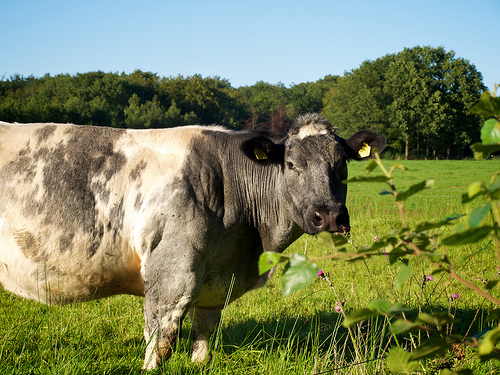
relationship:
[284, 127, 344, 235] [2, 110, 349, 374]
face of cow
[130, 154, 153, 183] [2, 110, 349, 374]
spot on cow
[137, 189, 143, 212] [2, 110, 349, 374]
spot on cow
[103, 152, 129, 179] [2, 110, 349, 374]
spot on cow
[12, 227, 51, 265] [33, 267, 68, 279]
spot next to spot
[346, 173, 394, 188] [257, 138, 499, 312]
leaf on branch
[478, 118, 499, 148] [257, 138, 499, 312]
leaf on branch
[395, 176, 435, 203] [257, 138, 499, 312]
leaf on branch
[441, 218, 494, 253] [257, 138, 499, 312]
leaf on branch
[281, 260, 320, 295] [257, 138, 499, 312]
leaf on branch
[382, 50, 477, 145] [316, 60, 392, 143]
tree next to tree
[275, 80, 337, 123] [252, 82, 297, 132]
tree next to tree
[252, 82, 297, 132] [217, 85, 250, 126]
tree next to tree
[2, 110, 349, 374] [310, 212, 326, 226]
cow has nostril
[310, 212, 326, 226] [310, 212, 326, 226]
nostril has nostril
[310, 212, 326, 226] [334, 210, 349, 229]
nostril has nostril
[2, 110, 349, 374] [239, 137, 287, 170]
cow has right ear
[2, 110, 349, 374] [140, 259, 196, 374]
cow has leg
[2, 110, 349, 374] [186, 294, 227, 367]
cow has leg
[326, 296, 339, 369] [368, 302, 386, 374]
grass leaf next to grass leaf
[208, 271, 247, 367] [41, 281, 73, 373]
grass leaf next to grass leaf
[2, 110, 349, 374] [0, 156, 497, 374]
cow standing in meadow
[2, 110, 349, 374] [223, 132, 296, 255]
cow has neck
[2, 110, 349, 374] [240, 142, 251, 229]
cow has wrinkle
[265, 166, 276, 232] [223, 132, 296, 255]
wrinkle along neck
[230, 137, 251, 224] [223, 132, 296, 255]
wrinkle along neck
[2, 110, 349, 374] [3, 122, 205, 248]
cow has back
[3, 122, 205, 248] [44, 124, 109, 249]
back has marking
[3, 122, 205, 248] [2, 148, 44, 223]
back has marking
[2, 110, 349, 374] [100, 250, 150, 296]
cow has rusty colored patch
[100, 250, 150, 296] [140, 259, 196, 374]
rusty colored patch behind leg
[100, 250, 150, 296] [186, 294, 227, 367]
rusty colored patch behind leg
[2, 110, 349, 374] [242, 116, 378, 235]
cow has head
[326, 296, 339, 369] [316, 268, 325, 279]
grass leaf has flower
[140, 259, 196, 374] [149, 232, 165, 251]
leg has indentation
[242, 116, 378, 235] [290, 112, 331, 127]
head has hair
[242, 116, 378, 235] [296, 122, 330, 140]
head has crown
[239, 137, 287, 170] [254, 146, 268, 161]
right ear has tag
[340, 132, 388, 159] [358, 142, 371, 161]
left ear has tag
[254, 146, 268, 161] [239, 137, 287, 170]
tag inside right ear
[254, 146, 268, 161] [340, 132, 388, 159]
tag inside left ear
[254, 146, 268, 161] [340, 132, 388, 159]
tag in left ear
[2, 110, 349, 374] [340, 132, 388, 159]
cow has left ear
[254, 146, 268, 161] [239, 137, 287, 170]
tag in right ear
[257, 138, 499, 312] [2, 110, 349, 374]
branch in front of cow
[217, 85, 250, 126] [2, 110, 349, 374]
tree behind cow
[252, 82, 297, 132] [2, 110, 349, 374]
tree behind cow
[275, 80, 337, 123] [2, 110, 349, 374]
tree behind cow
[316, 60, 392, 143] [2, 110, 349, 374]
tree behind cow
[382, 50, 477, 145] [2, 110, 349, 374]
tree behind cow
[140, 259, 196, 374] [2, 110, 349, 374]
leg on front of cow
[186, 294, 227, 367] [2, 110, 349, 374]
leg on front of cow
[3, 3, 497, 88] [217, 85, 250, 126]
sky above tree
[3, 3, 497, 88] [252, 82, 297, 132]
sky above tree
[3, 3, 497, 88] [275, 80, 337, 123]
sky above tree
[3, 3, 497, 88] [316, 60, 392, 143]
sky above tree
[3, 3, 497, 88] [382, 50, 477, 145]
sky above tree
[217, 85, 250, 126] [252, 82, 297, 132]
tree next to tree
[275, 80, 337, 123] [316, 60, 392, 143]
tree next to tree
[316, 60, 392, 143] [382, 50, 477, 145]
tree next to tree